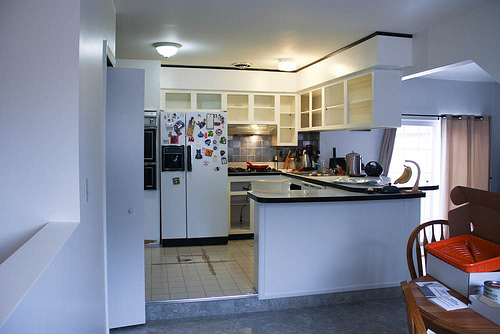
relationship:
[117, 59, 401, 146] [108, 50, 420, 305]
cabinet inside of kitchen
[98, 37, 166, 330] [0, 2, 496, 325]
door in room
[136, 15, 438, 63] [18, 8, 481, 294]
ceiling in room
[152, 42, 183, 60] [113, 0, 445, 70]
light on ceiling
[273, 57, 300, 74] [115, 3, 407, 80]
light on ceiling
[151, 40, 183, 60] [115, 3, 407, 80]
light on ceiling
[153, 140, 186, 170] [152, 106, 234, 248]
dispenser on fridge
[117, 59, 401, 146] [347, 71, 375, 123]
cabinet with door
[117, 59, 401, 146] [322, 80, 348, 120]
cabinet on door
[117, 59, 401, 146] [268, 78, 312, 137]
cabinet on door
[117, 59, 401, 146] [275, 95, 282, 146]
cabinet on door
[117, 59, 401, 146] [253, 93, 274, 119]
cabinet on door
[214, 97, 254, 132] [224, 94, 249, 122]
cabinet on door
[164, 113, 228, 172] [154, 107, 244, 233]
magnet on fridge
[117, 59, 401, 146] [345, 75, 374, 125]
cabinet on door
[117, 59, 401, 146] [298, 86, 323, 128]
cabinet on glass door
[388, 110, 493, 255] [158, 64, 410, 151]
glass door on cabinet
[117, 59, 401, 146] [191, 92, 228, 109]
cabinet on door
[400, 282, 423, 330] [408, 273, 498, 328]
chair by table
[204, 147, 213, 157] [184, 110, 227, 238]
magnet on fridge door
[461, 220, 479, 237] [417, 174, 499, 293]
cutout in box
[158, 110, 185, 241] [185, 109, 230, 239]
white door on refrigerator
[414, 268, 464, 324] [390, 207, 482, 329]
table with chairs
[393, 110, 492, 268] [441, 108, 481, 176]
window with curtain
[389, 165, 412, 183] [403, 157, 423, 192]
bananas hanging on holder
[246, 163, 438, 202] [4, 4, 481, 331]
counter in photo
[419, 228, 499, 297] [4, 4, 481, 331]
tray in photo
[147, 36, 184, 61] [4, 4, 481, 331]
bulb in photo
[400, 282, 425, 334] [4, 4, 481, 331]
chair in photo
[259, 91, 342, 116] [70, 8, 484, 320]
shelves in room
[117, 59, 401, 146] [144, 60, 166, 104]
cabinet with door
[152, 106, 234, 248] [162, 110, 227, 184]
fridge covered magnets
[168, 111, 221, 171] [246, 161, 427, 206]
glare on tile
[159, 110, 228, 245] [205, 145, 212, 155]
fridge with magnet